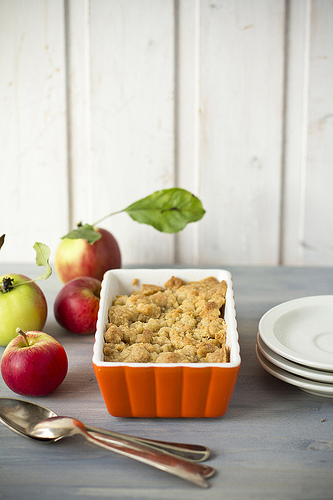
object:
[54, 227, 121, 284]
apple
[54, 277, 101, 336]
apple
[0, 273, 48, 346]
apple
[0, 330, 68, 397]
apple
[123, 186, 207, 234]
leaves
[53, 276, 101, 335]
fruit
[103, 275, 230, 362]
crust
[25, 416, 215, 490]
spoon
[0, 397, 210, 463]
spoon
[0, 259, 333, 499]
ground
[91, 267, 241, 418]
container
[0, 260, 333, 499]
counter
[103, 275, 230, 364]
dessert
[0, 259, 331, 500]
table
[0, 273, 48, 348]
fruit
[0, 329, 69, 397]
fruit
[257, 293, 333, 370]
plate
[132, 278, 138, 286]
crumb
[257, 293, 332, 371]
dish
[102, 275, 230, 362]
apple crisp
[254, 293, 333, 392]
dish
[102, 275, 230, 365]
food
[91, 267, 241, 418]
pan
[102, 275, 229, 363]
oatmeal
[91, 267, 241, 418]
bowl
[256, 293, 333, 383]
plates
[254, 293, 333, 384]
dish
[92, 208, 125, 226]
stem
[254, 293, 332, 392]
saucers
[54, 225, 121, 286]
fruit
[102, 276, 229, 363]
breakfast